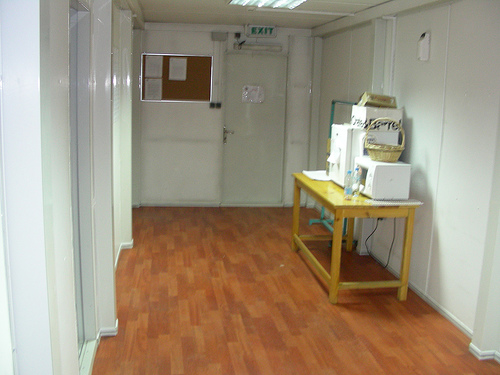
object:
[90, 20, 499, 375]
hallway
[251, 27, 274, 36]
exit sign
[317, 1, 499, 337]
wall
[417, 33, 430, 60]
paper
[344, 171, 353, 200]
bottles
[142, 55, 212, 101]
cork board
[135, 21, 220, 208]
wall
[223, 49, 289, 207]
door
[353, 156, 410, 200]
microwave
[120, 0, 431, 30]
ceiling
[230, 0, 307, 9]
light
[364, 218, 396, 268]
cord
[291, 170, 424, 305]
table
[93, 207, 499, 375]
hardwood flooring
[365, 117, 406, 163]
basket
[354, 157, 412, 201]
oven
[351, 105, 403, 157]
boxes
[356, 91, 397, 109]
boxes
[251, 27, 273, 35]
sign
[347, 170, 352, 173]
tops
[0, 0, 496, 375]
building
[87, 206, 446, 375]
floors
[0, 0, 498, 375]
hall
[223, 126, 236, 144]
handle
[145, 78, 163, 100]
paper